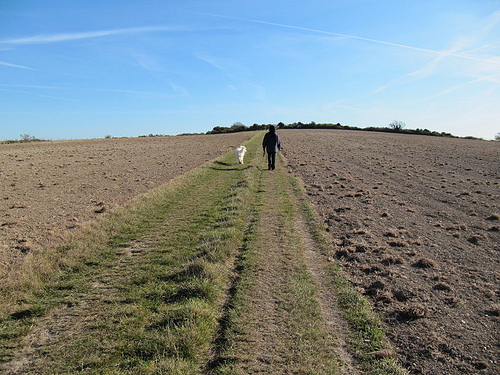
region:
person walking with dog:
[6, 5, 491, 366]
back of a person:
[258, 122, 285, 173]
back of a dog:
[233, 143, 248, 167]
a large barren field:
[8, 125, 494, 362]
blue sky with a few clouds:
[3, 2, 493, 118]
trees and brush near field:
[208, 118, 457, 138]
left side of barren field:
[3, 129, 263, 269]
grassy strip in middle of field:
[13, 133, 397, 370]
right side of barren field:
[279, 126, 494, 366]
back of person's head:
[264, 123, 276, 134]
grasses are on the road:
[146, 202, 248, 329]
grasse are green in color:
[168, 259, 258, 347]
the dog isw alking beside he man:
[231, 134, 261, 189]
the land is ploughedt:
[396, 202, 432, 347]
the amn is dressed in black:
[257, 120, 302, 185]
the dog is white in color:
[231, 136, 255, 171]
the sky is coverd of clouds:
[306, 64, 373, 91]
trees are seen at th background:
[237, 101, 297, 134]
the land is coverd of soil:
[60, 148, 104, 198]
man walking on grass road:
[259, 117, 286, 164]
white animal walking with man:
[230, 142, 252, 168]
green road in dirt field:
[191, 128, 313, 370]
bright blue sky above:
[115, 18, 372, 110]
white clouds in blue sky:
[395, 7, 480, 116]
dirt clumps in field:
[402, 256, 467, 311]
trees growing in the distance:
[213, 105, 464, 142]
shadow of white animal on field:
[202, 152, 233, 169]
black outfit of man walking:
[257, 132, 287, 170]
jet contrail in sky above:
[270, 18, 468, 72]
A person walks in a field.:
[260, 125, 281, 170]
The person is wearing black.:
[264, 133, 277, 148]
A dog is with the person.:
[234, 145, 246, 163]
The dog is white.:
[236, 144, 248, 163]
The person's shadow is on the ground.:
[206, 163, 258, 173]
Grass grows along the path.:
[131, 260, 211, 370]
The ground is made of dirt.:
[402, 170, 499, 301]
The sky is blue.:
[283, 3, 416, 22]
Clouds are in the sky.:
[451, 57, 498, 100]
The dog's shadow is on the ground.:
[210, 158, 239, 168]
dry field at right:
[277, 120, 497, 370]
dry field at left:
[1, 131, 256, 297]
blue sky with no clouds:
[0, 0, 492, 135]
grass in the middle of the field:
[0, 126, 407, 371]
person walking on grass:
[231, 121, 282, 166]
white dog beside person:
[232, 140, 248, 168]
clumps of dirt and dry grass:
[310, 116, 497, 324]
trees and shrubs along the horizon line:
[26, 125, 471, 140]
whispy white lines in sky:
[3, 20, 480, 112]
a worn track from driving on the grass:
[30, 120, 348, 367]